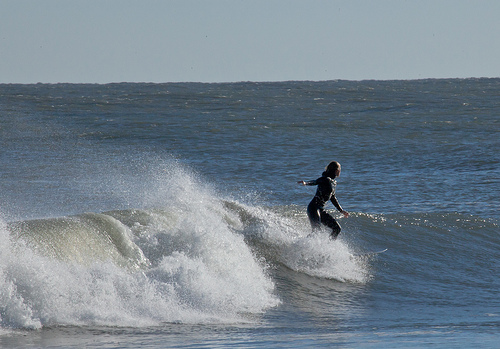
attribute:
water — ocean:
[3, 69, 498, 345]